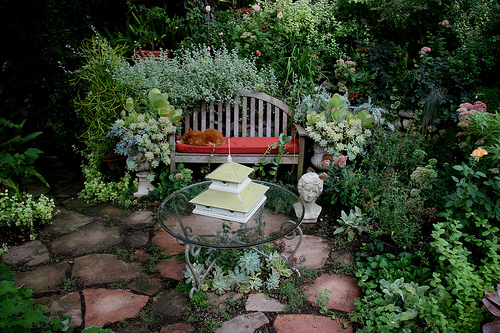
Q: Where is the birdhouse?
A: On the table.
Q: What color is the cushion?
A: Red.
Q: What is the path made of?
A: Stones.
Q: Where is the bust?
A: By the bench.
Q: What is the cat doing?
A: Sleeping.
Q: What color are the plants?
A: Green.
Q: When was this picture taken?
A: During the daytime.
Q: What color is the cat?
A: Orange.